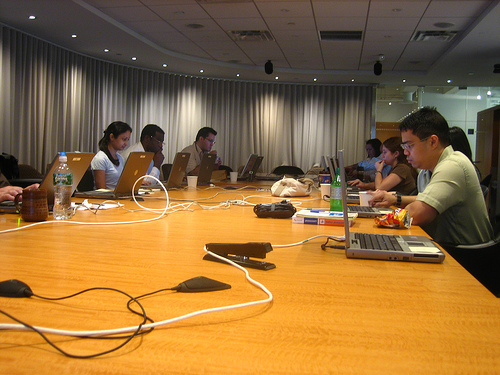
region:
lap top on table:
[47, 150, 87, 201]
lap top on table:
[113, 152, 157, 197]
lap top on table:
[168, 151, 201, 192]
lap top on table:
[194, 151, 217, 190]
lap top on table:
[240, 150, 264, 185]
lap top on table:
[323, 160, 440, 266]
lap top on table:
[322, 150, 338, 187]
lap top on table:
[317, 157, 329, 177]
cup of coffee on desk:
[183, 175, 205, 194]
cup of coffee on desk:
[227, 168, 241, 184]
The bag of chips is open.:
[365, 202, 420, 229]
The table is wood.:
[1, 132, 499, 372]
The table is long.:
[0, 137, 499, 373]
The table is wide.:
[1, 158, 496, 373]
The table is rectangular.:
[1, 161, 498, 373]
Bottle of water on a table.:
[51, 150, 79, 224]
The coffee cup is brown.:
[12, 183, 54, 227]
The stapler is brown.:
[203, 232, 278, 277]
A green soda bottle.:
[322, 162, 349, 217]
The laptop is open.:
[328, 144, 449, 278]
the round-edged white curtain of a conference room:
[0, 17, 387, 207]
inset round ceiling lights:
[0, 0, 499, 96]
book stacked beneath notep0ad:
[285, 203, 363, 231]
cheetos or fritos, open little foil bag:
[369, 203, 419, 233]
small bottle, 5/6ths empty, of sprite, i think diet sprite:
[325, 162, 351, 212]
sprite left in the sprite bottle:
[327, 203, 348, 217]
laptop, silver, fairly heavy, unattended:
[330, 141, 450, 271]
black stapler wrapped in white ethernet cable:
[184, 233, 294, 279]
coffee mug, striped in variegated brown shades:
[10, 180, 52, 229]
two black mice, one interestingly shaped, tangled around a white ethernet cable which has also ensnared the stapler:
[0, 222, 284, 369]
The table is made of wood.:
[311, 297, 438, 367]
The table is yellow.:
[320, 292, 453, 364]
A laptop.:
[333, 158, 458, 273]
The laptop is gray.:
[323, 143, 447, 271]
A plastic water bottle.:
[50, 145, 89, 227]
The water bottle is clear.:
[51, 145, 84, 227]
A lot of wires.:
[188, 190, 252, 220]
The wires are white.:
[191, 189, 252, 219]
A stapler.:
[189, 237, 282, 279]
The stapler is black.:
[198, 232, 285, 287]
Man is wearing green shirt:
[365, 102, 491, 244]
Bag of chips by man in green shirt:
[371, 205, 416, 229]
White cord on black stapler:
[0, 222, 345, 336]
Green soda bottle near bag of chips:
[327, 164, 347, 215]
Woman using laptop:
[91, 119, 134, 191]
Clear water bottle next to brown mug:
[52, 148, 74, 220]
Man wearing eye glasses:
[125, 117, 174, 187]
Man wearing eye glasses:
[177, 127, 222, 176]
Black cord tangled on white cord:
[0, 265, 232, 359]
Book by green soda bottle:
[291, 208, 356, 227]